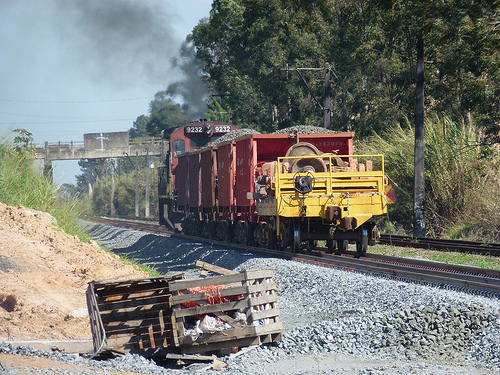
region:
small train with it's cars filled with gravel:
[134, 99, 399, 259]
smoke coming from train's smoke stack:
[75, 9, 238, 132]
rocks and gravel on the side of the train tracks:
[304, 257, 471, 336]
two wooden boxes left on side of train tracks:
[74, 251, 290, 358]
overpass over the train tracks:
[31, 114, 177, 171]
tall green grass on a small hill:
[5, 139, 87, 341]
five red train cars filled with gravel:
[176, 125, 270, 222]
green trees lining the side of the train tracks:
[86, 30, 476, 212]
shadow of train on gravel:
[101, 225, 279, 278]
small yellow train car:
[262, 145, 386, 247]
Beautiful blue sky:
[12, 3, 215, 135]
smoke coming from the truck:
[46, 0, 215, 117]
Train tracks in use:
[58, 119, 493, 329]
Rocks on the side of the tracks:
[86, 238, 496, 372]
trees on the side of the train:
[65, 0, 487, 230]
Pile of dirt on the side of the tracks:
[0, 213, 148, 335]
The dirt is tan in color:
[5, 200, 178, 329]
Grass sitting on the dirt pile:
[0, 140, 157, 267]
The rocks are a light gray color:
[38, 220, 499, 363]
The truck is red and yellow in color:
[153, 110, 395, 257]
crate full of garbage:
[154, 270, 294, 352]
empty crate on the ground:
[88, 277, 165, 359]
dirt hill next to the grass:
[5, 199, 67, 288]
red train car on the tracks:
[156, 115, 396, 252]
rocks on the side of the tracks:
[371, 302, 475, 354]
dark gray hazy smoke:
[127, 42, 197, 107]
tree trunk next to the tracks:
[400, 45, 430, 247]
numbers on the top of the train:
[182, 123, 235, 137]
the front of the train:
[275, 155, 384, 219]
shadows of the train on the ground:
[126, 231, 205, 267]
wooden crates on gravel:
[71, 270, 284, 361]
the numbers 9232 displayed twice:
[178, 123, 232, 136]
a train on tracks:
[99, 106, 411, 263]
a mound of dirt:
[6, 198, 151, 366]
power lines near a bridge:
[3, 79, 157, 166]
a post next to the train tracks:
[403, 22, 450, 248]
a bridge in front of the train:
[20, 119, 274, 219]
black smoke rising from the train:
[21, 0, 205, 115]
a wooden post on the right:
[268, 54, 367, 172]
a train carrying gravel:
[185, 112, 390, 223]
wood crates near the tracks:
[78, 267, 281, 352]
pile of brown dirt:
[3, 207, 140, 342]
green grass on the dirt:
[0, 138, 91, 243]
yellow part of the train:
[254, 150, 388, 258]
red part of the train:
[156, 117, 356, 237]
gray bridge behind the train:
[25, 133, 167, 223]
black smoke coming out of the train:
[55, 0, 214, 127]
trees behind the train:
[192, 2, 498, 242]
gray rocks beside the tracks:
[71, 219, 491, 372]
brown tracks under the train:
[81, 212, 499, 297]